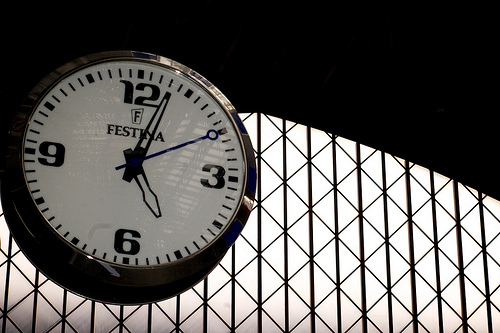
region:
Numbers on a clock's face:
[118, 76, 159, 111]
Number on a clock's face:
[113, 225, 140, 257]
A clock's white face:
[21, 62, 248, 268]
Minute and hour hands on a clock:
[122, 94, 169, 213]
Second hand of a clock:
[112, 126, 221, 169]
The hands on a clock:
[113, 90, 219, 220]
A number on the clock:
[37, 140, 65, 167]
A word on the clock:
[103, 122, 166, 142]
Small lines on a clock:
[20, 163, 91, 255]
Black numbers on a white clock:
[12, 51, 259, 281]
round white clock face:
[5, 40, 263, 307]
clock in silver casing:
[6, 41, 264, 315]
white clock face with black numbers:
[20, 58, 247, 272]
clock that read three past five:
[4, 47, 269, 308]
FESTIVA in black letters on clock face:
[102, 120, 167, 147]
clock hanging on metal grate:
[2, 40, 269, 305]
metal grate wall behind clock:
[6, 89, 498, 331]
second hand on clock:
[108, 128, 226, 175]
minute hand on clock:
[116, 90, 174, 183]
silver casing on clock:
[2, 42, 269, 306]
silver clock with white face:
[2, 43, 257, 311]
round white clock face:
[22, 58, 252, 271]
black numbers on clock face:
[17, 56, 252, 272]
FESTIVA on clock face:
[99, 120, 168, 147]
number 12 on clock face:
[117, 75, 163, 112]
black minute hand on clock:
[115, 87, 170, 184]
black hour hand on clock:
[119, 143, 164, 221]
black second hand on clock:
[110, 128, 228, 173]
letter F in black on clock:
[127, 104, 144, 128]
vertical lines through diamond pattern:
[285, 160, 405, 320]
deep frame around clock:
[6, 40, 256, 305]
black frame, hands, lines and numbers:
[6, 50, 256, 305]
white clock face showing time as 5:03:
[25, 65, 240, 265]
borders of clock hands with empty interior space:
[126, 86, 172, 216]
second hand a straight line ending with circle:
[110, 125, 217, 171]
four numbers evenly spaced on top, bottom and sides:
[25, 55, 245, 275]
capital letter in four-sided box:
[125, 101, 145, 126]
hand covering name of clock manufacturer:
[101, 121, 166, 142]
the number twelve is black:
[117, 78, 159, 109]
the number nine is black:
[38, 137, 66, 167]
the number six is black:
[113, 227, 140, 254]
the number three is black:
[199, 163, 228, 189]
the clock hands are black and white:
[113, 92, 217, 217]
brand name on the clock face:
[106, 106, 165, 143]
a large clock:
[6, 40, 258, 305]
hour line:
[82, 72, 97, 85]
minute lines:
[41, 204, 69, 237]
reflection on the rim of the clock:
[140, 52, 235, 113]